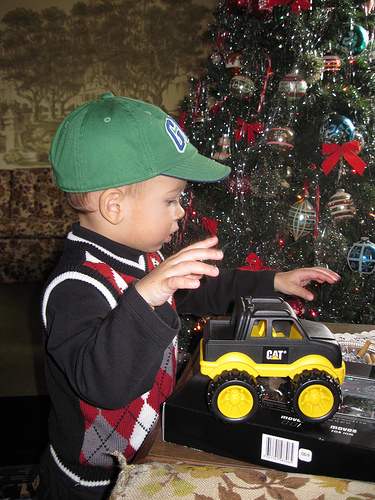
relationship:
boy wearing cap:
[39, 83, 197, 498] [55, 110, 185, 186]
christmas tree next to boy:
[205, 3, 369, 265] [39, 83, 197, 498]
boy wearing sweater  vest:
[39, 83, 197, 498] [48, 248, 144, 273]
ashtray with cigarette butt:
[349, 360, 374, 377] [360, 340, 368, 356]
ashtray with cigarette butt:
[349, 360, 374, 377] [367, 353, 370, 363]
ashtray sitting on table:
[349, 360, 374, 377] [331, 321, 369, 332]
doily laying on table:
[340, 334, 374, 342] [331, 321, 369, 332]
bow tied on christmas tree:
[319, 144, 364, 169] [205, 3, 369, 265]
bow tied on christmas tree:
[233, 114, 265, 139] [205, 3, 369, 265]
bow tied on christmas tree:
[249, 257, 263, 270] [205, 3, 369, 265]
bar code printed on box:
[262, 432, 304, 473] [165, 422, 370, 480]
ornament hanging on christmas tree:
[269, 125, 299, 153] [205, 3, 369, 265]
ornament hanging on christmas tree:
[348, 237, 373, 273] [205, 3, 369, 265]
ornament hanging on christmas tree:
[230, 75, 256, 104] [205, 3, 369, 265]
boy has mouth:
[39, 83, 197, 498] [167, 228, 181, 244]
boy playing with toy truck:
[39, 83, 197, 498] [203, 301, 336, 416]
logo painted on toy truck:
[263, 347, 292, 361] [203, 301, 336, 416]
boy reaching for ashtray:
[39, 83, 197, 498] [349, 360, 374, 377]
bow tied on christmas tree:
[274, 1, 316, 11] [205, 3, 369, 265]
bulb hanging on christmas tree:
[292, 192, 316, 242] [205, 3, 369, 265]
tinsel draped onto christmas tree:
[239, 170, 244, 212] [205, 3, 369, 265]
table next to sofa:
[331, 321, 369, 332] [127, 476, 341, 499]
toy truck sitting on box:
[203, 301, 336, 416] [165, 422, 370, 480]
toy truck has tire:
[203, 301, 336, 416] [206, 377, 257, 419]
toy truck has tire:
[203, 301, 336, 416] [288, 373, 343, 423]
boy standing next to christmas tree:
[39, 83, 197, 498] [205, 3, 369, 265]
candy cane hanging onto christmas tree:
[261, 63, 268, 112] [205, 3, 369, 265]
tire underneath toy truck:
[206, 377, 257, 419] [203, 301, 336, 416]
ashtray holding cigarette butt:
[349, 360, 374, 377] [360, 340, 368, 356]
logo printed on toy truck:
[263, 347, 292, 361] [203, 301, 336, 416]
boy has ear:
[39, 83, 197, 498] [95, 188, 130, 228]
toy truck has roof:
[203, 301, 336, 416] [247, 296, 287, 314]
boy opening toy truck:
[39, 83, 197, 498] [203, 301, 336, 416]